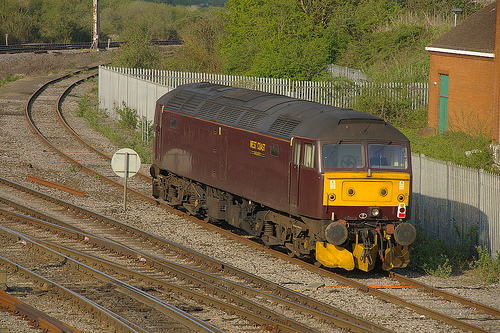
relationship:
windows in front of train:
[324, 141, 407, 173] [324, 146, 413, 215]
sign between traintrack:
[106, 141, 141, 178] [19, 79, 90, 149]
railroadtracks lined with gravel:
[24, 91, 82, 126] [39, 108, 71, 153]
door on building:
[430, 75, 451, 139] [419, 17, 494, 144]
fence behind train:
[250, 71, 421, 101] [151, 84, 417, 262]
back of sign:
[110, 140, 149, 205] [106, 141, 141, 178]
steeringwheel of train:
[341, 151, 361, 165] [324, 146, 413, 215]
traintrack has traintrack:
[19, 79, 90, 149] [19, 79, 90, 149]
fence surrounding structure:
[250, 71, 421, 101] [412, 32, 499, 146]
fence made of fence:
[250, 71, 421, 101] [250, 77, 427, 107]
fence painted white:
[250, 71, 421, 101] [260, 79, 366, 91]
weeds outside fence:
[105, 101, 138, 132] [250, 71, 421, 101]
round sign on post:
[106, 141, 141, 178] [98, 147, 143, 205]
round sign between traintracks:
[119, 150, 144, 177] [23, 94, 79, 260]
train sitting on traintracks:
[324, 146, 413, 215] [23, 103, 110, 218]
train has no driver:
[324, 146, 413, 215] [322, 133, 418, 168]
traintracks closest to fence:
[23, 103, 110, 218] [93, 71, 151, 111]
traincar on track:
[151, 84, 417, 262] [29, 86, 130, 179]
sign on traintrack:
[106, 141, 141, 178] [19, 79, 90, 149]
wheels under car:
[236, 214, 279, 243] [151, 84, 417, 262]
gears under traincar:
[186, 184, 234, 208] [157, 89, 250, 181]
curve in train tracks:
[19, 79, 90, 149] [23, 94, 79, 260]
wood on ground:
[308, 275, 328, 294] [164, 233, 317, 321]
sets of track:
[23, 103, 110, 218] [29, 86, 130, 179]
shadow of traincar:
[417, 194, 492, 250] [157, 89, 250, 181]